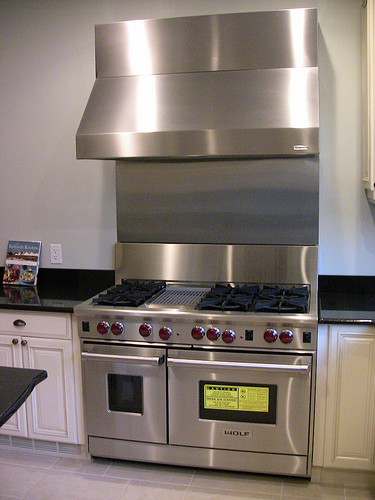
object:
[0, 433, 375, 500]
floor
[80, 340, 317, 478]
oven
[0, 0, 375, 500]
kitchen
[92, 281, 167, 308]
burners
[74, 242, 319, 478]
stove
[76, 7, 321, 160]
hood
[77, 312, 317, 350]
dials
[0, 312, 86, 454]
cabinents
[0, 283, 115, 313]
counter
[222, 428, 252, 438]
logo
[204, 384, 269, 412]
sticker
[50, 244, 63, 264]
outlet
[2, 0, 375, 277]
wall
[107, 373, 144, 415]
glass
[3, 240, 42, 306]
book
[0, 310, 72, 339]
drawer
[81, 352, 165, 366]
handle